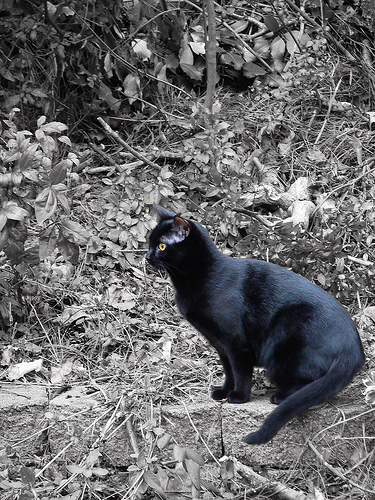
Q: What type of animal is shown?
A: Cat.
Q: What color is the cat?
A: Black.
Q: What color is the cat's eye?
A: Yellow.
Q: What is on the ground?
A: Leaves.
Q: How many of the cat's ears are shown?
A: 2.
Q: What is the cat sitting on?
A: Concrete.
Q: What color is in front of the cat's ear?
A: White.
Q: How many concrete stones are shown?
A: 3.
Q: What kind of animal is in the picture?
A: A cat.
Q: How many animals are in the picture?
A: 1.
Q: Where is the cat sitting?
A: AT a brick ledge.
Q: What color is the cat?
A: Black.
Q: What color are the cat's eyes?
A: Yellow.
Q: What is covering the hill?
A: Leaves.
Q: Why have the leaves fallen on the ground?
A: They are dead.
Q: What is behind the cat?
A: A hill.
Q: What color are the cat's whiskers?
A: White.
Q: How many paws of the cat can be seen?
A: 3.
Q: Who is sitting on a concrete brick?
A: A cat.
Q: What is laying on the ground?
A: Leaves.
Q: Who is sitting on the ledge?
A: A cat.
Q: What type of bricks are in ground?
A: Concrete.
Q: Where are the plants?
A: Background.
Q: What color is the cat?
A: Black.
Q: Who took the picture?
A: My sister.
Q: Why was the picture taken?
A: To capture the spirit of the cat.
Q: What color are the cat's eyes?
A: Yellow.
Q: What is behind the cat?
A: Trees and shrubs.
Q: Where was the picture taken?
A: In the backyard.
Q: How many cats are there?
A: One.